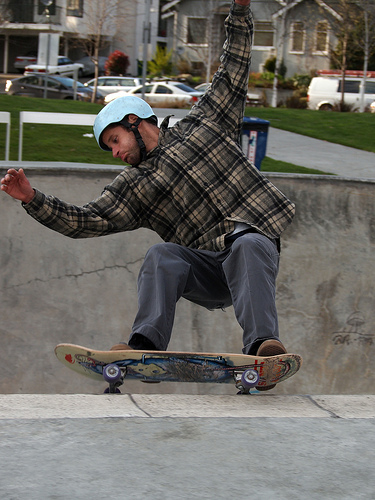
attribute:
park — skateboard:
[21, 1, 374, 347]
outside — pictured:
[286, 1, 371, 146]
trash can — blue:
[240, 115, 270, 170]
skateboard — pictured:
[53, 343, 301, 395]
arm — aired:
[194, 0, 255, 136]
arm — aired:
[0, 167, 136, 240]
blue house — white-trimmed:
[166, 1, 351, 95]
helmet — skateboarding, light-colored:
[81, 101, 145, 126]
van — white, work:
[307, 75, 372, 121]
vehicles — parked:
[1, 53, 373, 107]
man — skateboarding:
[2, 1, 288, 354]